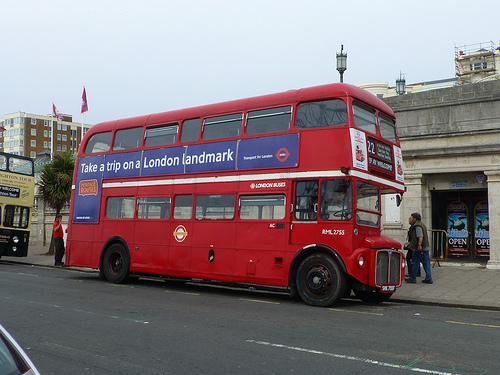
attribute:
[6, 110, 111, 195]
building — brown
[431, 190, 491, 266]
door — open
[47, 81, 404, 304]
shirt — red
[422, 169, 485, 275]
signs — blue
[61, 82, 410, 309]
bus — big, red, black, blue, white, yellow, double-decker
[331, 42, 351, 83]
light — tall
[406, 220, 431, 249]
jacket — tan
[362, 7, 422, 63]
clouds — white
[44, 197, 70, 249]
shirt — red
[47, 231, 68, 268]
pants — dark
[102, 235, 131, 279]
tire — back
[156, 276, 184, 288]
tire — back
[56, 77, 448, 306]
bus — yellow, double-decker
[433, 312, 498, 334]
yellowline — Yellow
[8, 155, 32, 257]
bus — black, yellow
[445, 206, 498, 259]
signs — blue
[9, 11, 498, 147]
sky — blue